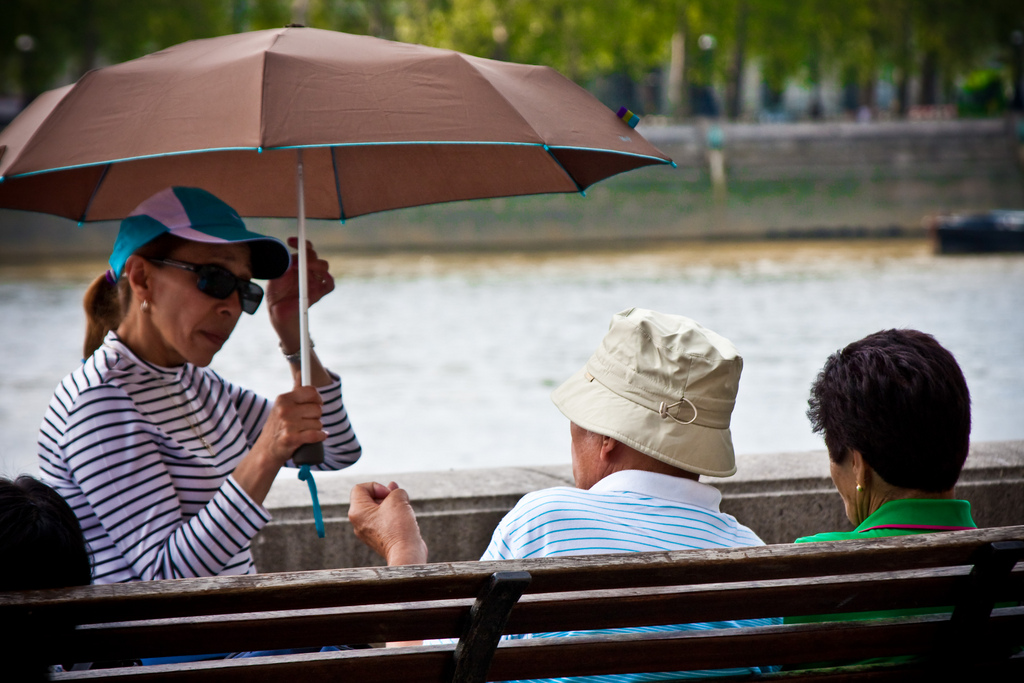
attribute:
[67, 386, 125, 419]
stripe — Black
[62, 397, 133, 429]
stripe — Black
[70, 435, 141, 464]
stripe — Black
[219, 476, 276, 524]
stripe — Black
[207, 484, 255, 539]
stripe — Black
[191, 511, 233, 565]
stripe — Black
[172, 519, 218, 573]
stripe — Black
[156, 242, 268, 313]
glasses — Sun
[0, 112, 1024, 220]
wall — Retaining